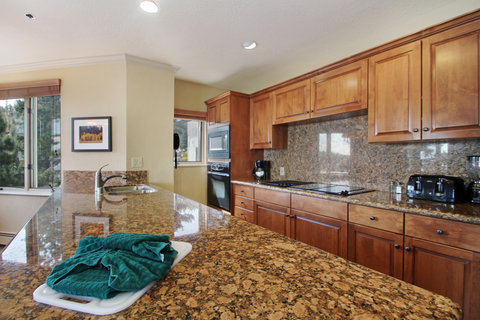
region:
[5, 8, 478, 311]
a kitchen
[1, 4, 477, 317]
a clean kitchen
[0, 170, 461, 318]
a granite countertops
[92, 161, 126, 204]
a faucet on the counter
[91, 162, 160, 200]
a faucet and sink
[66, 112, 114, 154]
a picture on the wall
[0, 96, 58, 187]
window on the wall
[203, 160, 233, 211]
a black oven on the wall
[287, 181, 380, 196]
a stove top on the counter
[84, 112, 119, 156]
a picture on a wall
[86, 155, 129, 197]
a faucet for the sink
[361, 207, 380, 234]
a knob on the cabinet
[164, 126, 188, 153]
a phone on the wall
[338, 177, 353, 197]
knob on the stove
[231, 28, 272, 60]
lights in the ceiling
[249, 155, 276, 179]
coffee pot in the corner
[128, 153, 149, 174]
a switch on the wall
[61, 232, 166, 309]
Green towel on counter.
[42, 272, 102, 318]
White cutting board on counter.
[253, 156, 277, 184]
Black coffee pot on counter.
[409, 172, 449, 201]
Large black toaster on counter.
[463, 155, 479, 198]
Blender sitting on counter.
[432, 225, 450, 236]
Gray knob on drawer.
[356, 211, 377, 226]
Gray knob on drawer.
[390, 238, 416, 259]
Gray knobs on cupboards.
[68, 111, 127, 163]
Black framed picture on wall.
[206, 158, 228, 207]
Black oven on built in wall.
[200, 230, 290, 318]
the table is tiled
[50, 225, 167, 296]
this is a towel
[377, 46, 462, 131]
these are the drawers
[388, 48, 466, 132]
the drawers are closed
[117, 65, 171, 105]
this is the wall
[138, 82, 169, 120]
the wall is cream in color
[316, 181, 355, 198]
this is the sink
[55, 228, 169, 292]
the towel is green in color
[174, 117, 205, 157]
the window is open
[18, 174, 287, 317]
island counter in center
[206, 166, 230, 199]
oven on the wall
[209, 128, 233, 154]
microwave above the oven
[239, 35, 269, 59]
light on the ceiling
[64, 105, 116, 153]
image on the wall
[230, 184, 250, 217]
drawers next to oven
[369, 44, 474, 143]
cabinets above the counter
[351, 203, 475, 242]
drawers below the counter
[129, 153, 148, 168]
outlet on the wall